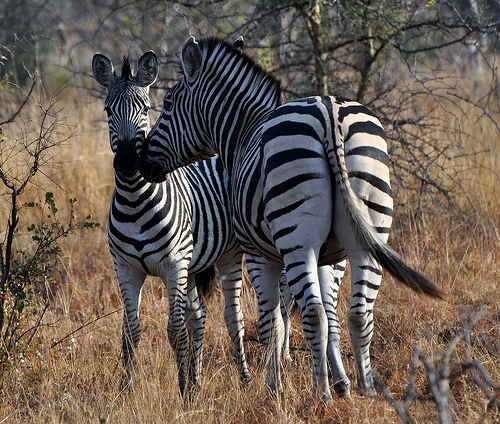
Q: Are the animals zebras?
A: Yes, all the animals are zebras.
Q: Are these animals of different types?
A: No, all the animals are zebras.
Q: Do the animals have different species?
A: No, all the animals are zebras.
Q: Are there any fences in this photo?
A: No, there are no fences.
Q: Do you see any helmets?
A: No, there are no helmets.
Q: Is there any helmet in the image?
A: No, there are no helmets.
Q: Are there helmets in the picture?
A: No, there are no helmets.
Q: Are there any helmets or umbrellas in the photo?
A: No, there are no helmets or umbrellas.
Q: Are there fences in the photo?
A: No, there are no fences.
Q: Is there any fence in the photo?
A: No, there are no fences.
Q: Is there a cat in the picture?
A: No, there are no cats.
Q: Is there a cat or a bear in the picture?
A: No, there are no cats or bears.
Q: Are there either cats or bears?
A: No, there are no cats or bears.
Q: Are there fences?
A: No, there are no fences.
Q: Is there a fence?
A: No, there are no fences.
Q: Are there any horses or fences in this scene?
A: No, there are no fences or horses.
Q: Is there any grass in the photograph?
A: Yes, there is grass.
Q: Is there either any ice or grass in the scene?
A: Yes, there is grass.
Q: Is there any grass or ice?
A: Yes, there is grass.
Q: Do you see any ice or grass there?
A: Yes, there is grass.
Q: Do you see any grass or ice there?
A: Yes, there is grass.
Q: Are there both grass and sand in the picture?
A: No, there is grass but no sand.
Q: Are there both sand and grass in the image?
A: No, there is grass but no sand.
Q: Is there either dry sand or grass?
A: Yes, there is dry grass.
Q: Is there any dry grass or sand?
A: Yes, there is dry grass.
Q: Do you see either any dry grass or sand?
A: Yes, there is dry grass.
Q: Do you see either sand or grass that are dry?
A: Yes, the grass is dry.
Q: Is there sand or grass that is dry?
A: Yes, the grass is dry.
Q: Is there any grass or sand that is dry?
A: Yes, the grass is dry.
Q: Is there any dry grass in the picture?
A: Yes, there is dry grass.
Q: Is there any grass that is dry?
A: Yes, there is grass that is dry.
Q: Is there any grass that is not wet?
A: Yes, there is dry grass.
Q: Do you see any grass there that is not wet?
A: Yes, there is dry grass.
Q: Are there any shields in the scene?
A: No, there are no shields.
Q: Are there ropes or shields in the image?
A: No, there are no shields or ropes.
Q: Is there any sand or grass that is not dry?
A: No, there is grass but it is dry.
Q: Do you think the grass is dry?
A: Yes, the grass is dry.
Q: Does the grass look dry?
A: Yes, the grass is dry.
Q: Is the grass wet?
A: No, the grass is dry.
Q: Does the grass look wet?
A: No, the grass is dry.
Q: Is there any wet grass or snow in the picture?
A: No, there is grass but it is dry.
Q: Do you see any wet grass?
A: No, there is grass but it is dry.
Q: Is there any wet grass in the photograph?
A: No, there is grass but it is dry.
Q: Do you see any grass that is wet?
A: No, there is grass but it is dry.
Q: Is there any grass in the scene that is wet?
A: No, there is grass but it is dry.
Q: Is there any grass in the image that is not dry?
A: No, there is grass but it is dry.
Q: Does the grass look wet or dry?
A: The grass is dry.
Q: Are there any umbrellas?
A: No, there are no umbrellas.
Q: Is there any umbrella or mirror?
A: No, there are no umbrellas or mirrors.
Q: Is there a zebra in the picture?
A: Yes, there is a zebra.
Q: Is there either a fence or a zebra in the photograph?
A: Yes, there is a zebra.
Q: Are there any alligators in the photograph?
A: No, there are no alligators.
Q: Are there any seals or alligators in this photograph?
A: No, there are no alligators or seals.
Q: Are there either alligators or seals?
A: No, there are no alligators or seals.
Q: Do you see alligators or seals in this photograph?
A: No, there are no alligators or seals.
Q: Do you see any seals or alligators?
A: No, there are no alligators or seals.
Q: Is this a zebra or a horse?
A: This is a zebra.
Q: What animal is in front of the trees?
A: The zebra is in front of the trees.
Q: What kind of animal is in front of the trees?
A: The animal is a zebra.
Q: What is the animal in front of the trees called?
A: The animal is a zebra.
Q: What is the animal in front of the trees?
A: The animal is a zebra.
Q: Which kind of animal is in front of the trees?
A: The animal is a zebra.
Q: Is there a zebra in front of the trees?
A: Yes, there is a zebra in front of the trees.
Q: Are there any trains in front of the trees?
A: No, there is a zebra in front of the trees.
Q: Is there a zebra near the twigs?
A: Yes, there is a zebra near the twigs.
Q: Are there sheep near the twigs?
A: No, there is a zebra near the twigs.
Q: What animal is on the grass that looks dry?
A: The animal is a zebra.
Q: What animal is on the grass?
A: The animal is a zebra.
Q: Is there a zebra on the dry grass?
A: Yes, there is a zebra on the grass.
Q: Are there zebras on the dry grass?
A: Yes, there is a zebra on the grass.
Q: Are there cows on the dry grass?
A: No, there is a zebra on the grass.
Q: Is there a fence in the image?
A: No, there are no fences.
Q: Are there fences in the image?
A: No, there are no fences.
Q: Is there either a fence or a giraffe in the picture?
A: No, there are no fences or giraffes.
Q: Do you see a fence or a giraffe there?
A: No, there are no fences or giraffes.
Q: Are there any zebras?
A: Yes, there is a zebra.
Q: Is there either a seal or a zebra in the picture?
A: Yes, there is a zebra.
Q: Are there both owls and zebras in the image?
A: No, there is a zebra but no owls.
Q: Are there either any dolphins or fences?
A: No, there are no fences or dolphins.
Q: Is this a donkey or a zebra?
A: This is a zebra.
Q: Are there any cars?
A: No, there are no cars.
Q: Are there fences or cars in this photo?
A: No, there are no cars or fences.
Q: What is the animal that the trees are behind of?
A: The animal is a zebra.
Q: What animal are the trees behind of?
A: The trees are behind the zebra.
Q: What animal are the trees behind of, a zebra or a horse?
A: The trees are behind a zebra.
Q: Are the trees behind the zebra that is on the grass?
A: Yes, the trees are behind the zebra.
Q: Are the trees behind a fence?
A: No, the trees are behind the zebra.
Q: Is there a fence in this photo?
A: No, there are no fences.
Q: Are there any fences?
A: No, there are no fences.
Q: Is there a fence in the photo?
A: No, there are no fences.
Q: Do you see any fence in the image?
A: No, there are no fences.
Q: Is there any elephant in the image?
A: No, there are no elephants.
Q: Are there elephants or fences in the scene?
A: No, there are no elephants or fences.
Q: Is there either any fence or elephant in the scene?
A: No, there are no elephants or fences.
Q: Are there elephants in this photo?
A: No, there are no elephants.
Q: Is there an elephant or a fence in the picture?
A: No, there are no elephants or fences.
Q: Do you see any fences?
A: No, there are no fences.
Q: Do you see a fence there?
A: No, there are no fences.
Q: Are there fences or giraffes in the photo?
A: No, there are no fences or giraffes.